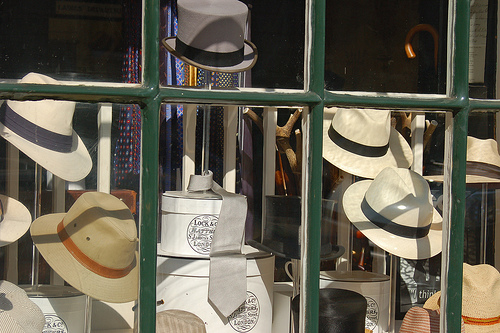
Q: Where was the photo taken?
A: It was taken at the display.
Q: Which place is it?
A: It is a display.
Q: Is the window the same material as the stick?
A: No, the window is made of glass and the stick is made of wood.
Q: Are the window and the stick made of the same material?
A: No, the window is made of glass and the stick is made of wood.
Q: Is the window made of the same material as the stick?
A: No, the window is made of glass and the stick is made of wood.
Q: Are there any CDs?
A: No, there are no cds.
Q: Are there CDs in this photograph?
A: No, there are no cds.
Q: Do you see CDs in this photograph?
A: No, there are no cds.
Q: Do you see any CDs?
A: No, there are no cds.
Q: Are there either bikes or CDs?
A: No, there are no CDs or bikes.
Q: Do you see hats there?
A: Yes, there is a hat.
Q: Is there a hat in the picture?
A: Yes, there is a hat.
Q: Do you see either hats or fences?
A: Yes, there is a hat.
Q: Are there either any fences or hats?
A: Yes, there is a hat.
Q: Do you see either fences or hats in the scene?
A: Yes, there is a hat.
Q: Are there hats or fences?
A: Yes, there is a hat.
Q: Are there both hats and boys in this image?
A: No, there is a hat but no boys.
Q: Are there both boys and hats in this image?
A: No, there is a hat but no boys.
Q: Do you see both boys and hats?
A: No, there is a hat but no boys.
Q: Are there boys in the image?
A: No, there are no boys.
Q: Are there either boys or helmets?
A: No, there are no boys or helmets.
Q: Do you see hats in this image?
A: Yes, there is a hat.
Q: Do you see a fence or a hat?
A: Yes, there is a hat.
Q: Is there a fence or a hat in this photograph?
A: Yes, there is a hat.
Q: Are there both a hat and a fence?
A: No, there is a hat but no fences.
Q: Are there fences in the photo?
A: No, there are no fences.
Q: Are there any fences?
A: No, there are no fences.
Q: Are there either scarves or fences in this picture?
A: No, there are no fences or scarves.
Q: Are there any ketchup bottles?
A: No, there are no ketchup bottles.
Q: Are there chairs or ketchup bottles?
A: No, there are no ketchup bottles or chairs.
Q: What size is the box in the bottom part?
A: The box is large.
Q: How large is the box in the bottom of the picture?
A: The box is large.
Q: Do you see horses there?
A: No, there are no horses.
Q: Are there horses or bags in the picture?
A: No, there are no horses or bags.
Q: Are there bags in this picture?
A: No, there are no bags.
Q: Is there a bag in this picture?
A: No, there are no bags.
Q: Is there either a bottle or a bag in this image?
A: No, there are no bags or bottles.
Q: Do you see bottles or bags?
A: No, there are no bags or bottles.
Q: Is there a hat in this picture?
A: Yes, there is a hat.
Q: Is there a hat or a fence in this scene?
A: Yes, there is a hat.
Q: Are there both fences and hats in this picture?
A: No, there is a hat but no fences.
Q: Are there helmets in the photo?
A: No, there are no helmets.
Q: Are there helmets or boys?
A: No, there are no helmets or boys.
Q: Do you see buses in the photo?
A: No, there are no buses.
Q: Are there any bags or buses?
A: No, there are no buses or bags.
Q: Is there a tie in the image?
A: Yes, there is a tie.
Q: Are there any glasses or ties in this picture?
A: Yes, there is a tie.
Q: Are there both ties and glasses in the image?
A: No, there is a tie but no glasses.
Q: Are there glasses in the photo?
A: No, there are no glasses.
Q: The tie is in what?
A: The tie is in the window.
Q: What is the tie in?
A: The tie is in the window.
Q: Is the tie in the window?
A: Yes, the tie is in the window.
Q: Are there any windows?
A: Yes, there is a window.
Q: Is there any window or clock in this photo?
A: Yes, there is a window.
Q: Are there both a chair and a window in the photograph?
A: No, there is a window but no chairs.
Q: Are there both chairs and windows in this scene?
A: No, there is a window but no chairs.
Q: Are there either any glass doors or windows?
A: Yes, there is a glass window.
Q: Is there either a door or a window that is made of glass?
A: Yes, the window is made of glass.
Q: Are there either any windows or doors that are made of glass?
A: Yes, the window is made of glass.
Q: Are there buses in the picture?
A: No, there are no buses.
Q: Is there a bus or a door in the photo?
A: No, there are no buses or doors.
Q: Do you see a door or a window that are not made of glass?
A: No, there is a window but it is made of glass.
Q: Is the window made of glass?
A: Yes, the window is made of glass.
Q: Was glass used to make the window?
A: Yes, the window is made of glass.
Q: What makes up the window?
A: The window is made of glass.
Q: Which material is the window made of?
A: The window is made of glass.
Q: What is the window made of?
A: The window is made of glass.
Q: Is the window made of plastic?
A: No, the window is made of glass.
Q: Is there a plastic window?
A: No, there is a window but it is made of glass.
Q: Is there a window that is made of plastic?
A: No, there is a window but it is made of glass.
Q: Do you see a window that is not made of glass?
A: No, there is a window but it is made of glass.